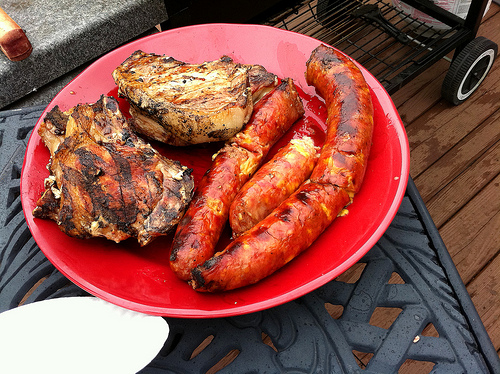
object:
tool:
[0, 21, 33, 60]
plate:
[20, 23, 409, 320]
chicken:
[30, 97, 193, 245]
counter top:
[0, 0, 169, 110]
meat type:
[29, 93, 190, 245]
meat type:
[110, 49, 280, 144]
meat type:
[191, 43, 373, 294]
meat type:
[229, 134, 322, 237]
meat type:
[168, 76, 306, 281]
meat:
[110, 48, 275, 146]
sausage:
[186, 45, 379, 292]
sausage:
[227, 135, 318, 241]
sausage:
[165, 76, 306, 281]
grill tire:
[441, 35, 498, 106]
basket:
[263, 1, 466, 93]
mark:
[188, 256, 219, 295]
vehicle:
[378, 260, 445, 357]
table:
[0, 105, 498, 373]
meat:
[30, 92, 198, 245]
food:
[31, 42, 372, 292]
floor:
[178, 5, 499, 372]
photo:
[2, 2, 499, 372]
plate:
[0, 291, 171, 374]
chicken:
[111, 47, 277, 148]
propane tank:
[377, 0, 481, 41]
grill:
[270, 1, 461, 88]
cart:
[275, 3, 498, 108]